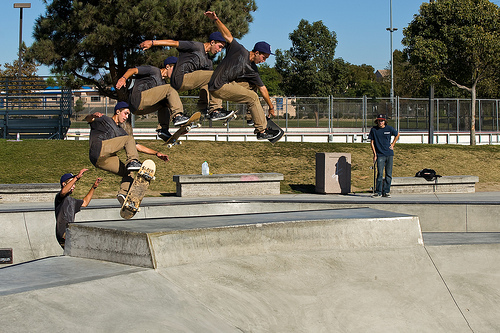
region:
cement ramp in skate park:
[92, 201, 499, 331]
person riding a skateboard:
[210, 18, 304, 150]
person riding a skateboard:
[170, 19, 240, 139]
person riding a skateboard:
[115, 58, 207, 168]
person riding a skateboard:
[82, 90, 176, 229]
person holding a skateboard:
[352, 103, 411, 218]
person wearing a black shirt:
[220, 39, 280, 111]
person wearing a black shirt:
[176, 32, 216, 94]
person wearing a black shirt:
[115, 65, 163, 107]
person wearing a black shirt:
[94, 109, 144, 162]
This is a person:
[362, 102, 408, 216]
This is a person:
[85, 96, 164, 198]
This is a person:
[120, 51, 196, 142]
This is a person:
[142, 12, 237, 122]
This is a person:
[205, 5, 303, 157]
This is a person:
[51, 152, 123, 280]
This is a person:
[82, 94, 163, 209]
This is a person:
[117, 42, 214, 154]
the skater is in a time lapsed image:
[5, 10, 283, 245]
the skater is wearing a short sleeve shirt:
[206, 37, 261, 92]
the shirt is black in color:
[205, 40, 260, 90]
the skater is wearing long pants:
[210, 80, 270, 135]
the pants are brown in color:
[210, 76, 270, 131]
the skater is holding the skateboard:
[257, 105, 287, 145]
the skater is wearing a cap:
[252, 39, 275, 55]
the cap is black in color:
[252, 39, 277, 56]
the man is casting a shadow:
[337, 110, 396, 198]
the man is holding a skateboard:
[367, 157, 381, 192]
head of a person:
[252, 29, 287, 67]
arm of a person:
[255, 85, 279, 99]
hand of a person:
[266, 108, 284, 115]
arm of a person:
[203, 2, 239, 50]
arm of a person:
[146, 37, 176, 54]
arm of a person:
[120, 65, 136, 85]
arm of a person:
[75, 183, 106, 213]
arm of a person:
[130, 134, 154, 163]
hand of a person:
[155, 150, 169, 165]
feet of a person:
[119, 163, 145, 180]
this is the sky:
[339, 8, 391, 39]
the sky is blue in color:
[340, 0, 371, 27]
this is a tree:
[293, 18, 335, 87]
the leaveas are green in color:
[298, 28, 333, 85]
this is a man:
[364, 111, 402, 186]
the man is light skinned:
[58, 184, 82, 194]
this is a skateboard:
[128, 169, 159, 213]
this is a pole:
[383, 12, 398, 90]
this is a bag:
[412, 157, 443, 185]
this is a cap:
[252, 40, 276, 50]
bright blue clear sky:
[1, 0, 433, 80]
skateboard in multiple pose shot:
[39, 5, 298, 258]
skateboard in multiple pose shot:
[43, 0, 297, 249]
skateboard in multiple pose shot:
[38, 5, 285, 250]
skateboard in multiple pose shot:
[47, 5, 292, 252]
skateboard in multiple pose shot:
[37, 11, 288, 254]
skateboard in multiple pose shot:
[46, 6, 296, 260]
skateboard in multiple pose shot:
[38, 6, 293, 267]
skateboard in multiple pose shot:
[37, 2, 297, 249]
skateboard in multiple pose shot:
[36, 5, 292, 257]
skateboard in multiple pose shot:
[33, 3, 293, 250]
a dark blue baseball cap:
[248, 39, 279, 58]